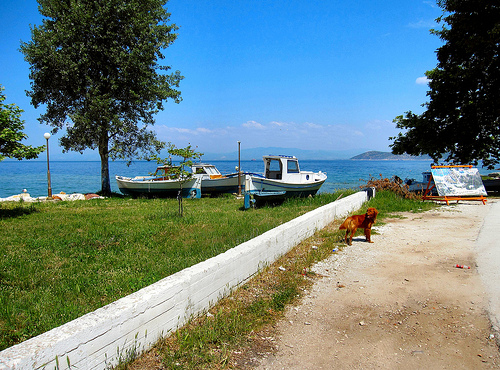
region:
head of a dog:
[365, 199, 387, 221]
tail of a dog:
[338, 216, 353, 239]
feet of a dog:
[338, 228, 362, 247]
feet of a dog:
[363, 228, 385, 238]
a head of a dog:
[360, 200, 380, 220]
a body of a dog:
[332, 205, 365, 242]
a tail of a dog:
[329, 222, 353, 234]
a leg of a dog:
[343, 235, 359, 242]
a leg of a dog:
[365, 230, 390, 242]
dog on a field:
[322, 198, 390, 266]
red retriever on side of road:
[338, 205, 378, 245]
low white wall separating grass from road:
[4, 184, 376, 369]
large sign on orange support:
[420, 161, 488, 206]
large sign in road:
[424, 162, 491, 210]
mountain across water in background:
[347, 147, 437, 158]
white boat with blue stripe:
[202, 152, 328, 207]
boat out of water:
[198, 152, 329, 195]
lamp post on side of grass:
[40, 130, 55, 197]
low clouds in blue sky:
[156, 112, 398, 158]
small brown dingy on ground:
[245, 188, 287, 210]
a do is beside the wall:
[337, 201, 404, 261]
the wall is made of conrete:
[187, 184, 327, 284]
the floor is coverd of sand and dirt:
[379, 309, 436, 368]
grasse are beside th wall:
[138, 232, 205, 257]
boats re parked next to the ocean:
[119, 149, 305, 224]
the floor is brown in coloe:
[353, 265, 415, 368]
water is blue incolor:
[338, 139, 391, 194]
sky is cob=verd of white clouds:
[210, 99, 274, 133]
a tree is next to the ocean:
[45, 69, 122, 216]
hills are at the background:
[361, 133, 428, 163]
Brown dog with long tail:
[338, 208, 378, 248]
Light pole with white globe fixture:
[40, 128, 55, 198]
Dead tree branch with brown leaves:
[363, 175, 420, 202]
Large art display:
[427, 159, 490, 204]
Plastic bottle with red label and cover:
[451, 261, 473, 271]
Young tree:
[168, 143, 198, 219]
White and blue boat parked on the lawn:
[241, 151, 328, 205]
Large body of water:
[322, 158, 430, 173]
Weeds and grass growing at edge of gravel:
[191, 310, 282, 362]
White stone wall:
[109, 278, 188, 348]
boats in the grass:
[115, 151, 327, 211]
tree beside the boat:
[16, 1, 185, 209]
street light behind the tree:
[40, 127, 56, 195]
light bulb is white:
[42, 130, 52, 141]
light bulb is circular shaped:
[43, 129, 51, 141]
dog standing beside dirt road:
[336, 204, 378, 244]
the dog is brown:
[338, 205, 377, 242]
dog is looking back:
[340, 205, 378, 243]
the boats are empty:
[115, 152, 330, 209]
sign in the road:
[426, 161, 491, 199]